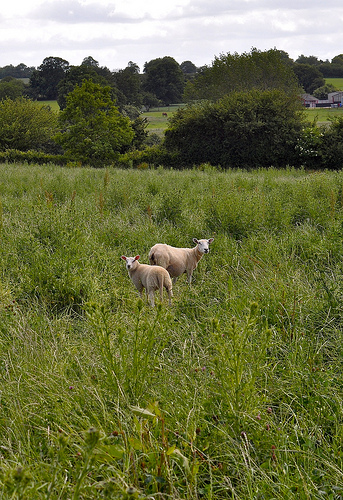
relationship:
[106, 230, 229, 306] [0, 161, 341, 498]
sheep in field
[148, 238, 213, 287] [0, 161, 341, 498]
sheep in field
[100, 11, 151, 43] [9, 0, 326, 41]
white clouds on blue sky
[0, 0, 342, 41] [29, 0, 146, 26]
blue sky full of cloud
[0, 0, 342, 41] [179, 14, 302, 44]
blue sky full of cloud